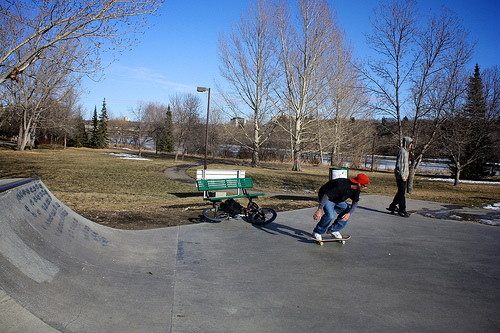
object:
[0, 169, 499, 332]
ground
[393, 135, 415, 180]
hoodie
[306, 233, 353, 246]
skateboard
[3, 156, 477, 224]
ground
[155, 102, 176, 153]
tree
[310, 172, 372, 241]
man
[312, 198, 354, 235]
jeans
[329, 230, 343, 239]
shoe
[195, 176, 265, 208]
bench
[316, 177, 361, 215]
shirt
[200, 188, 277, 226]
bicycle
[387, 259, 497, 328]
ground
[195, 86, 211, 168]
light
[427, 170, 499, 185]
snow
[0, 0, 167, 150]
tree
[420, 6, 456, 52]
no leaves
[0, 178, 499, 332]
ramp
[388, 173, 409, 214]
jeans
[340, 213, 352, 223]
hands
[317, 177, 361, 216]
jacket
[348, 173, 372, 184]
cap